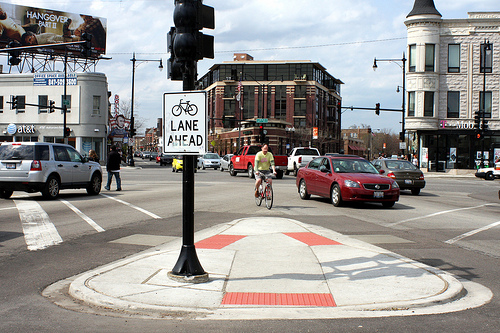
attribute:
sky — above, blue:
[243, 3, 337, 43]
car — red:
[283, 132, 404, 224]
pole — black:
[156, 72, 219, 258]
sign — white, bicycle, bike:
[153, 83, 219, 163]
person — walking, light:
[69, 134, 150, 244]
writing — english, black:
[176, 125, 203, 145]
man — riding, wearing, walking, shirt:
[228, 129, 292, 226]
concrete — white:
[266, 245, 305, 286]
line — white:
[129, 187, 173, 237]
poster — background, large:
[24, 7, 109, 73]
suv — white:
[267, 133, 328, 184]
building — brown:
[237, 47, 320, 121]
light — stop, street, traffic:
[243, 115, 278, 145]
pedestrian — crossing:
[91, 130, 145, 191]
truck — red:
[219, 134, 277, 190]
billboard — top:
[4, 13, 82, 48]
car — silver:
[53, 167, 97, 193]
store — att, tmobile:
[433, 124, 472, 165]